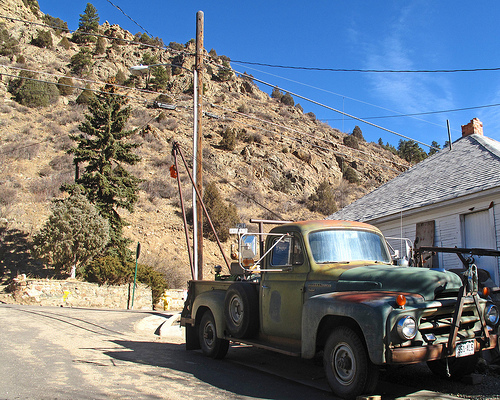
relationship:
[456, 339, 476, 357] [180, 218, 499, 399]
license plate on truck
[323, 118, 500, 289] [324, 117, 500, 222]
building has a grey roof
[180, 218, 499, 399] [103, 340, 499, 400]
truck has a shadow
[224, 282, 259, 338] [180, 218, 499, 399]
spare tire on truck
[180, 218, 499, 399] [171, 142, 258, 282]
truck has towing equipment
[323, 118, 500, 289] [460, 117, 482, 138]
building has a chimney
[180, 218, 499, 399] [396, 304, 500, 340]
truck has headlights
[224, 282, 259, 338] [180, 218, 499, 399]
spare tire attached to truck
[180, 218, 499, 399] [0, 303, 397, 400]
truck on road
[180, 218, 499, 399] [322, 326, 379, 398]
truck has a front tire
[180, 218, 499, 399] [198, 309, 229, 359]
truck has a rear tire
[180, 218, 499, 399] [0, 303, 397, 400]
truck sitting on road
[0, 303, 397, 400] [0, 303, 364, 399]
road has dirt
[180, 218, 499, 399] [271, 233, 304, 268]
truck has a window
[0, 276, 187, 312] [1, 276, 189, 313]
wall made of stone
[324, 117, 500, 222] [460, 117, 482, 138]
roof has a chimney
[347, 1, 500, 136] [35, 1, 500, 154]
cloud in blue sky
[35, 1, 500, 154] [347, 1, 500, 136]
blue sky has a cloud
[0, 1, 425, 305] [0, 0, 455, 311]
hill has trees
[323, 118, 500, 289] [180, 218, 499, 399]
building beside truck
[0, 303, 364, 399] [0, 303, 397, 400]
dirt on road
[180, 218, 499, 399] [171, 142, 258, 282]
truck can be used to tow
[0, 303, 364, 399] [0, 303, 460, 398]
dirt on road